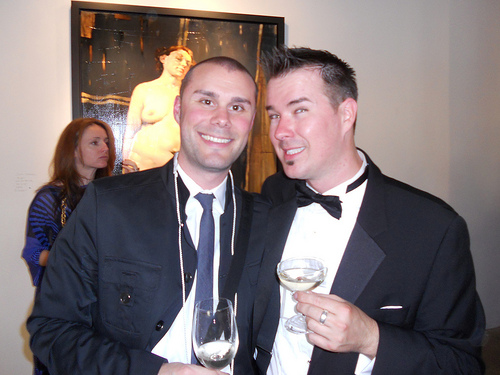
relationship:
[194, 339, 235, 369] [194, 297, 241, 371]
liquid in glass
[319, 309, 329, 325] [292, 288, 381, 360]
band on hand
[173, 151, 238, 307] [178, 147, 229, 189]
string around neck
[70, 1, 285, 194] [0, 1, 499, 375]
picture on wall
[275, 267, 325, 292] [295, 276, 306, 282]
liquid with olive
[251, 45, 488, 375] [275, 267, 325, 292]
man has liquid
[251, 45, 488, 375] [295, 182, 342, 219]
man has bow tie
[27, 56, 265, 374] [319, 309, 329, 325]
man has band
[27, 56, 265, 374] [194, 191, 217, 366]
man has tie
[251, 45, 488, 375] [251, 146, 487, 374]
man has suit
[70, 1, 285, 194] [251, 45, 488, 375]
picture behind man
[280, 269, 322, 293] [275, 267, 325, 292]
liquid in liquid